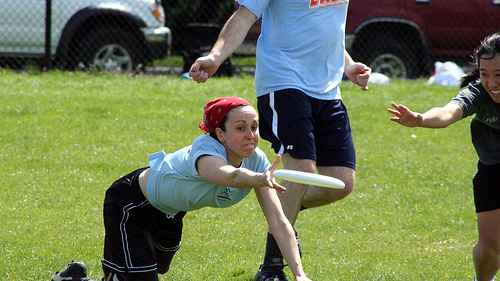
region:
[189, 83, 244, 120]
The red bandana on the woman.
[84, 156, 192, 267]
The woman is wearing a black pant.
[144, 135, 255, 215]
The woman is wearing a white shirt.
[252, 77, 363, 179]
the shorts are black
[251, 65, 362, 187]
the shorts are black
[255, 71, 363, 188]
the shorts are black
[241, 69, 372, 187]
the shorts are black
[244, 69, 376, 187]
the shorts are black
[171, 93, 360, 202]
girl reaching for the frisbee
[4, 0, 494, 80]
cars parked behind metal fencing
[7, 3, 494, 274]
people playing on ground covered with green grass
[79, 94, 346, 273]
woman on ground reaching for white frisbee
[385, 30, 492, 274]
woman smiling and reaching out with arm and hand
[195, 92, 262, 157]
woman wearing red bandanna over head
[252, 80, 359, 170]
person wearing dark shorts with white side stripe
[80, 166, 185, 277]
dark shorts with double lines of white top stitching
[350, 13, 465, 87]
filled white plastic bags near black tire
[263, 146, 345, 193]
thumb up with palm open for frisbee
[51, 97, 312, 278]
player diving for the frisbee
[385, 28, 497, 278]
player diving for the frisbee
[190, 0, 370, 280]
man running for the frisbee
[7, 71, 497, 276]
playing ultimate on the green grass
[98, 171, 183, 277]
athletic shorts are black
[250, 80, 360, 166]
athletic shorts are black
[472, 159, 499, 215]
athletic shorts are black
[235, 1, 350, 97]
blue shirt on ultimate player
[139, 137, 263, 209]
blue shirt on ultimate player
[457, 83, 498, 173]
black shirt on ultimate player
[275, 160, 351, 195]
A white Frisbee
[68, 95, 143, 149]
Green grass in sunlight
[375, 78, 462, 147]
An extending right arm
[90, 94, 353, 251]
A girl lunging to throw a Frisbee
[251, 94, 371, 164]
Blue shorts with a white stripe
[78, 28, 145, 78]
A tire with a silver hupcap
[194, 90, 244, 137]
A red bandana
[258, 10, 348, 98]
A pale white T-shirt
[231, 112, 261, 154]
A woman's face showing exertion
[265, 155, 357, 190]
a frisbee flying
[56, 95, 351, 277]
a girl sends a frisbee flying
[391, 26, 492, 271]
a girl reaches for the frisbee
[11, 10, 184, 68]
a white truck is parked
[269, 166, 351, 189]
A Frisbee in the air.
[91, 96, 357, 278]
A woman catching a Frisbee.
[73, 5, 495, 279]
A group of people playing Frisbee.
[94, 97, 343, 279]
A woman with a red headscarf reaches for the Frisbee.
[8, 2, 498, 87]
Cars parked outside the fence.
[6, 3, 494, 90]
A metal fence at the edge of the field.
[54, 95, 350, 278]
The woman reaching is falling.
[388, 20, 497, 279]
A woman with long hair reaching for the Frisbee.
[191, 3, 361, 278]
A man in a grey shirt running.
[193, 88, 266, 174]
The woman has a red bandanna on her head.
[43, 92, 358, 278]
A woman reaching for a Frisbee.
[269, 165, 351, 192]
A frisbee in the air.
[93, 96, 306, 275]
A woman waring a red headscarf.